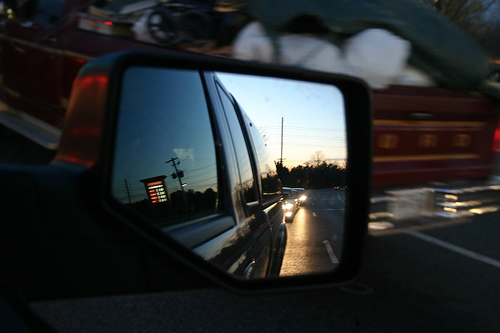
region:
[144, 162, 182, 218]
Reflection of gas station in the window.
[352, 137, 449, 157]
Reflection of gas station in the window.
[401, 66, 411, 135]
Reflection of gas station in the window.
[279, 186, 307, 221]
cars with headlights on in side mirror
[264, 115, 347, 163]
electric pole and wires in mirror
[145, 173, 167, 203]
red and green lighted sign in mirror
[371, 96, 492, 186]
tailgate on a Ford truck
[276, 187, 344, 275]
paved road with white stripes in mirror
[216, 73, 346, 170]
clear sky at sunset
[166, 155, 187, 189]
electric pole with transformers in mirror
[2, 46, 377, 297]
side mirror on vehicle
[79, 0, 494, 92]
several items in the bed of a truck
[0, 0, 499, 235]
maroon Ford truck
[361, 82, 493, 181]
The red tailgate is for a Ford, the F is hidden.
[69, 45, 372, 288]
A vehicle mirror has a reflection in it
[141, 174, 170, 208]
A red and white sign is lit up.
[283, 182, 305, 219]
Cars with headlights on.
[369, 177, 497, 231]
A chrome bumper has a light on.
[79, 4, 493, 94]
A truck is loaded with household goods.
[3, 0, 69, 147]
The door and running board of a truck are red and blurry.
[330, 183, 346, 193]
Two red lights are on.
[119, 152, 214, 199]
Two poles have wires on them.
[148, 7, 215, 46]
Two wheels have spokes.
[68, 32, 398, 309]
the rear view mirror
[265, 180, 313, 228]
the headlights are on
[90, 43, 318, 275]
the car is reflected in the mirror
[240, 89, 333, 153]
the sun is going down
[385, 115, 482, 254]
the background is blurry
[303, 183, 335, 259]
the street is grey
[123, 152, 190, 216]
a lit sign reflected in the window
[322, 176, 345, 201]
the brake lights in the distance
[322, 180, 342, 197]
the brake lights are red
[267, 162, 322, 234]
two cars headlights are on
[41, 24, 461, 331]
the view from a mirror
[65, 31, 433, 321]
the car is an suv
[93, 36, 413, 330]
two cars behind the car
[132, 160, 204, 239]
a gas station sign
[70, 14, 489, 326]
there is a truck ahead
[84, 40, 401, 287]
the time is dusk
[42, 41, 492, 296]
the cars have lights on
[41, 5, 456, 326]
the red light reflects on plastic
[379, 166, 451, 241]
a blurry license plate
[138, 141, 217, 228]
a power line near gas station